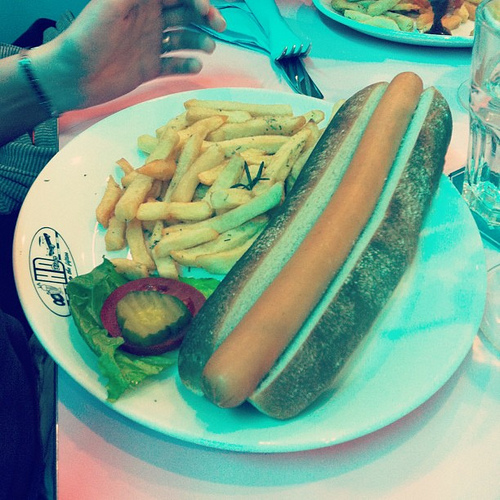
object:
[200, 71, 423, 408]
hotdog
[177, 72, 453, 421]
bun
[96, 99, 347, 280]
french fries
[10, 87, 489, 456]
plate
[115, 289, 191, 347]
pickle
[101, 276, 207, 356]
tomato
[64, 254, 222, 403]
lettuce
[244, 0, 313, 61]
fork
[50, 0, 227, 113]
hand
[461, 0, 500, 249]
glass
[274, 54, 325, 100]
knife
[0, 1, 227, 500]
person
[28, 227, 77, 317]
logo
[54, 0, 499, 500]
table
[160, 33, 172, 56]
wedding band